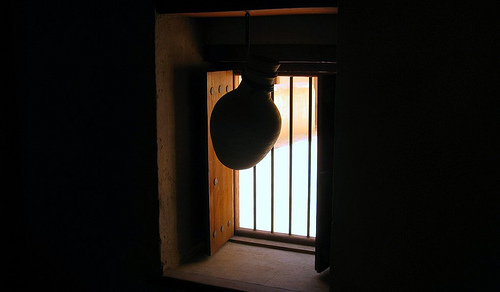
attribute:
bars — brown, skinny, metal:
[233, 75, 318, 244]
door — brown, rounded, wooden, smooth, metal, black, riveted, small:
[202, 62, 332, 273]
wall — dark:
[3, 3, 500, 285]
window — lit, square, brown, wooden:
[238, 72, 319, 244]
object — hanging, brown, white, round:
[209, 51, 287, 174]